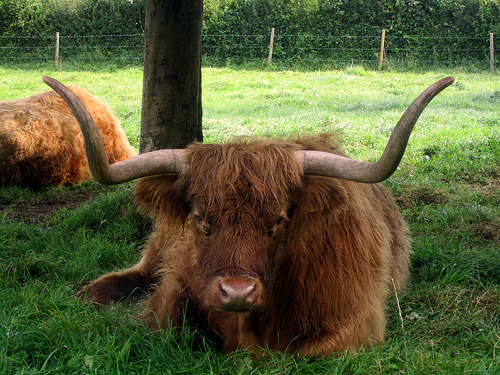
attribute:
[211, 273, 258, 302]
nose — light brown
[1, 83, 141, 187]
bull — brown 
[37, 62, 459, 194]
horns — long 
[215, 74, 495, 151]
grass — green 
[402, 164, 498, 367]
grass — green 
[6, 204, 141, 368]
grass — green 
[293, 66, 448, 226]
horns — light brown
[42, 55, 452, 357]
cow — furry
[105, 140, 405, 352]
hair — brown, long 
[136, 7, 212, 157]
tree trunk — brown 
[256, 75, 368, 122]
grass — green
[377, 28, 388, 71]
post — brown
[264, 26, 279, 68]
post — brown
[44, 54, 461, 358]
bull — brown 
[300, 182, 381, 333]
fur — brown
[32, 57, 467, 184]
long horns — long 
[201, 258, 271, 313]
snout — brown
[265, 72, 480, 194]
horn — curved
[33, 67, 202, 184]
horn — curved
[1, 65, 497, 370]
ground — grass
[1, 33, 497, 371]
grass — long , green 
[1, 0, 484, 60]
bushes — green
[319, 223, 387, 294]
fur — brown